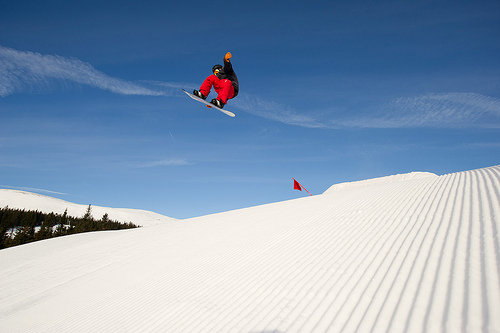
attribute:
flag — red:
[282, 161, 317, 194]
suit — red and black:
[200, 60, 243, 102]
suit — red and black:
[195, 57, 282, 128]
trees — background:
[5, 196, 145, 261]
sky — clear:
[319, 45, 426, 130]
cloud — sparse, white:
[1, 45, 498, 130]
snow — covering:
[124, 215, 465, 292]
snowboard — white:
[181, 88, 234, 119]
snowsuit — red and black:
[189, 61, 249, 100]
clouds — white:
[1, 42, 496, 153]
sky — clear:
[342, 41, 437, 111]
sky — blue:
[304, 27, 434, 102]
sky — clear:
[2, 1, 499, 219]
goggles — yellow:
[211, 68, 219, 75]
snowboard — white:
[180, 84, 243, 121]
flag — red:
[292, 178, 304, 192]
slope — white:
[0, 164, 497, 331]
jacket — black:
[212, 62, 237, 92]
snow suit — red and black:
[198, 61, 239, 105]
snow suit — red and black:
[197, 57, 239, 103]